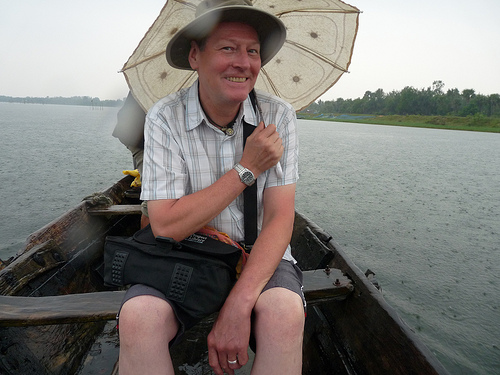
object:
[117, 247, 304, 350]
shorts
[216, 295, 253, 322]
wrist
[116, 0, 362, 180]
umbrella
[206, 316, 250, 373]
hand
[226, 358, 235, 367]
wedding band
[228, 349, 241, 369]
finger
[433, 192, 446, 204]
ripples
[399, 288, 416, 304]
rain drops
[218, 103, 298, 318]
arm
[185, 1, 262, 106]
head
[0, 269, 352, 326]
wood plank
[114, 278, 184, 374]
leg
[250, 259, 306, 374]
leg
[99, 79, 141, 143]
droplet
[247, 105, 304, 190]
finger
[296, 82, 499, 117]
trees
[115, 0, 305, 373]
man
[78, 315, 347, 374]
water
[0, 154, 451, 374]
boat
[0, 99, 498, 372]
water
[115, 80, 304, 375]
body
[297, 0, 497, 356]
rain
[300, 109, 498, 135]
grass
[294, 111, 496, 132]
field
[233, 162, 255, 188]
wrist watch